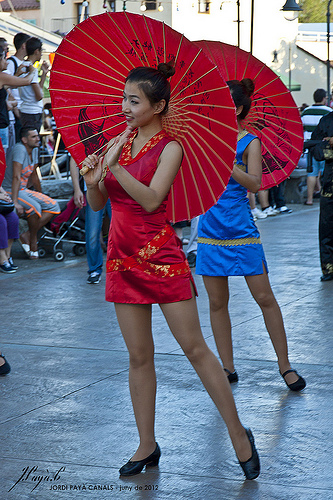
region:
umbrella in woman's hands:
[46, 6, 240, 225]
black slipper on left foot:
[228, 421, 261, 481]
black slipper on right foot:
[119, 438, 163, 477]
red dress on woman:
[97, 125, 204, 309]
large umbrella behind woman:
[44, 6, 240, 227]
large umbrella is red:
[48, 7, 240, 226]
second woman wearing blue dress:
[195, 125, 270, 278]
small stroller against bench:
[37, 184, 91, 261]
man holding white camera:
[20, 60, 30, 71]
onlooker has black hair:
[24, 34, 43, 54]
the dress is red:
[83, 127, 191, 323]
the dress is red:
[91, 121, 194, 331]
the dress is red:
[81, 119, 192, 354]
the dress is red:
[100, 131, 195, 323]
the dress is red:
[85, 125, 204, 349]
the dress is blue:
[193, 119, 265, 283]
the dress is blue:
[208, 127, 298, 300]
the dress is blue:
[205, 126, 265, 295]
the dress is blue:
[194, 119, 282, 309]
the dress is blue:
[188, 115, 267, 280]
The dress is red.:
[108, 158, 196, 289]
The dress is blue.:
[200, 154, 258, 275]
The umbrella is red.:
[50, 28, 191, 154]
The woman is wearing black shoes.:
[116, 438, 263, 484]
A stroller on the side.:
[38, 195, 84, 260]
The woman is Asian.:
[99, 60, 174, 141]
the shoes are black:
[117, 427, 276, 488]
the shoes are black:
[105, 429, 291, 488]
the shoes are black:
[112, 433, 281, 492]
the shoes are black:
[106, 428, 275, 489]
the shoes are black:
[96, 418, 280, 492]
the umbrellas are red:
[42, 11, 316, 262]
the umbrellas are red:
[50, 12, 323, 214]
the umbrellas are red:
[43, 22, 325, 267]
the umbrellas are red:
[43, 13, 300, 231]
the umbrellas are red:
[51, 6, 314, 250]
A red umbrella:
[92, 30, 155, 61]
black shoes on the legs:
[108, 426, 273, 484]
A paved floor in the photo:
[50, 335, 108, 419]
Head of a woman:
[115, 56, 177, 131]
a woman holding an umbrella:
[48, 11, 263, 480]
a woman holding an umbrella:
[183, 37, 305, 392]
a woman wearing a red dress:
[80, 56, 264, 483]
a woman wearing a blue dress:
[194, 76, 307, 393]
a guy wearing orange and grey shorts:
[5, 129, 58, 260]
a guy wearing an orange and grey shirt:
[2, 127, 59, 258]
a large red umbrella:
[47, 10, 239, 225]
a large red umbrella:
[186, 40, 305, 194]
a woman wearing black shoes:
[79, 63, 259, 481]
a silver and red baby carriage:
[37, 187, 86, 259]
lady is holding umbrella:
[82, 60, 258, 479]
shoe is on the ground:
[118, 441, 162, 476]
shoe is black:
[117, 442, 160, 476]